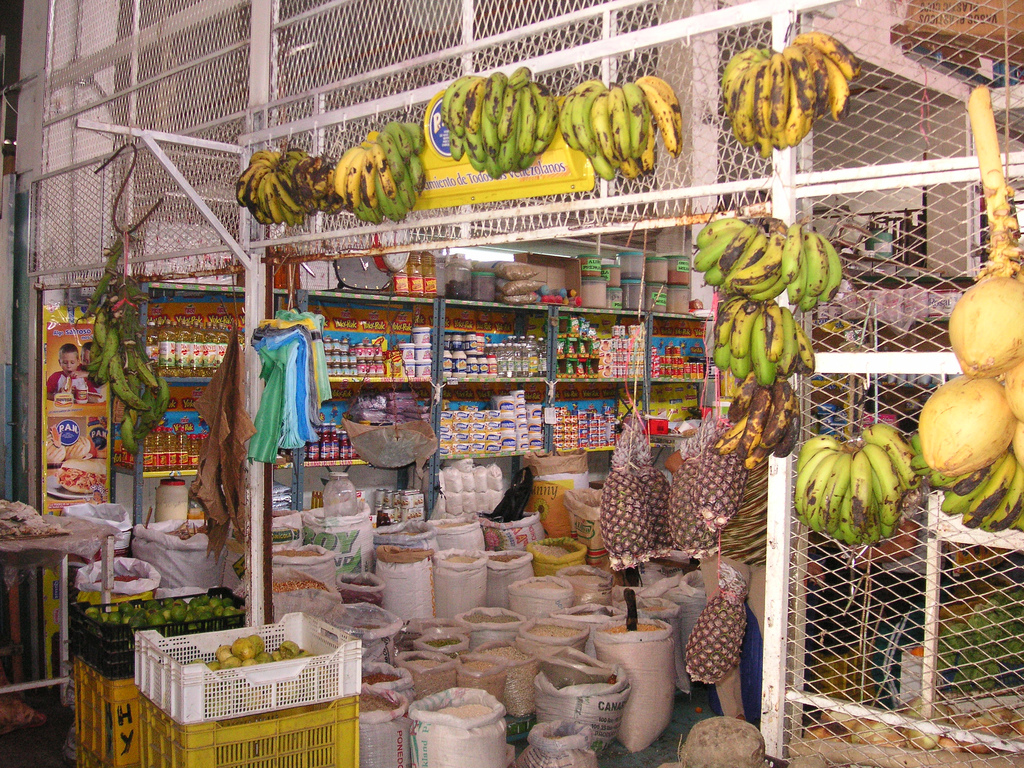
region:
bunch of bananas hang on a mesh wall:
[435, 59, 556, 178]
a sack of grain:
[412, 672, 498, 764]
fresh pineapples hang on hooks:
[606, 403, 658, 578]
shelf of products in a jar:
[446, 314, 552, 385]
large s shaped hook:
[79, 138, 172, 230]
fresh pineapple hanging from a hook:
[683, 571, 756, 695]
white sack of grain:
[596, 602, 667, 749]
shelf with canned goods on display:
[300, 293, 436, 398]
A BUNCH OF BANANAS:
[723, 306, 825, 373]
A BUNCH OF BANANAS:
[713, 367, 818, 472]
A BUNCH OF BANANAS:
[689, 230, 854, 303]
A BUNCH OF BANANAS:
[742, 37, 866, 121]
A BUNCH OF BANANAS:
[432, 57, 547, 175]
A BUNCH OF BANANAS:
[328, 88, 426, 229]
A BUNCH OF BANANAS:
[85, 320, 168, 422]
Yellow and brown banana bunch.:
[708, 28, 863, 162]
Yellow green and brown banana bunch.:
[555, 75, 686, 189]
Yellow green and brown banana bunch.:
[437, 63, 556, 182]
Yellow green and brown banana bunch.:
[323, 119, 426, 224]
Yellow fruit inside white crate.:
[128, 607, 367, 721]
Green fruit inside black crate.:
[68, 584, 255, 676]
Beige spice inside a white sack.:
[405, 683, 508, 766]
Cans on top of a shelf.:
[547, 308, 646, 384]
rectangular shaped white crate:
[135, 614, 361, 723]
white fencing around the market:
[44, 13, 1018, 766]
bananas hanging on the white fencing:
[237, 19, 1007, 554]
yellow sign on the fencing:
[347, 87, 600, 231]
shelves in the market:
[117, 235, 740, 599]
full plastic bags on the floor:
[287, 516, 698, 766]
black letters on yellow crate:
[119, 699, 142, 757]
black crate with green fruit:
[64, 594, 257, 697]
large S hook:
[88, 140, 171, 232]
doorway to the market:
[275, 237, 743, 766]